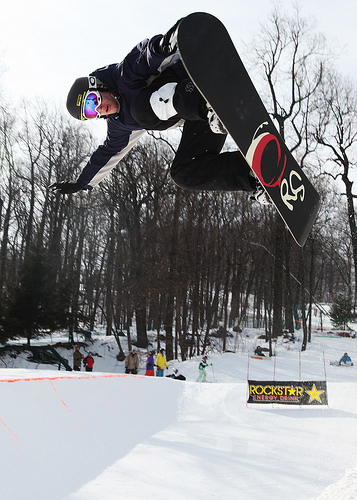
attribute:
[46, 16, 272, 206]
man — sideways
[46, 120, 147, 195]
arm — extended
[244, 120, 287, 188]
emblem — red, white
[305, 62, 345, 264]
tree — bare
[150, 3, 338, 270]
snowboard — black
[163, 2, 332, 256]
snowboard — black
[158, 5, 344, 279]
snowboard — black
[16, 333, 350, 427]
snow — white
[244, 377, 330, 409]
sign — red, yellow, black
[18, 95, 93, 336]
trees — leafless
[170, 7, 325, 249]
snowboard — airborne, black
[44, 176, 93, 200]
glove — black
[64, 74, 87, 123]
hat — black